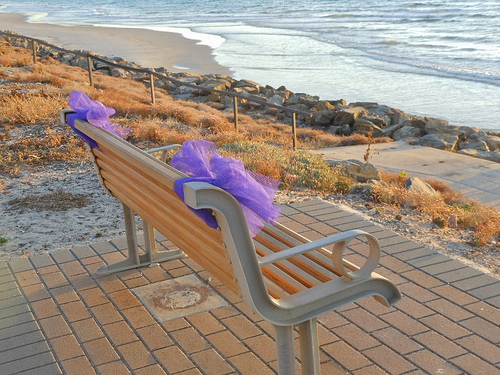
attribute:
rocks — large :
[45, 31, 497, 177]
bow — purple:
[165, 132, 291, 249]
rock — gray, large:
[404, 114, 473, 156]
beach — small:
[4, 5, 240, 81]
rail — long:
[9, 29, 339, 149]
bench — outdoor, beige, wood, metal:
[65, 93, 415, 365]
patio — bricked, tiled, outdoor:
[3, 209, 493, 373]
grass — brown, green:
[225, 119, 356, 204]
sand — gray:
[20, 198, 89, 239]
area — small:
[0, 154, 123, 261]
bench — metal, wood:
[37, 79, 420, 369]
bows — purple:
[57, 85, 279, 224]